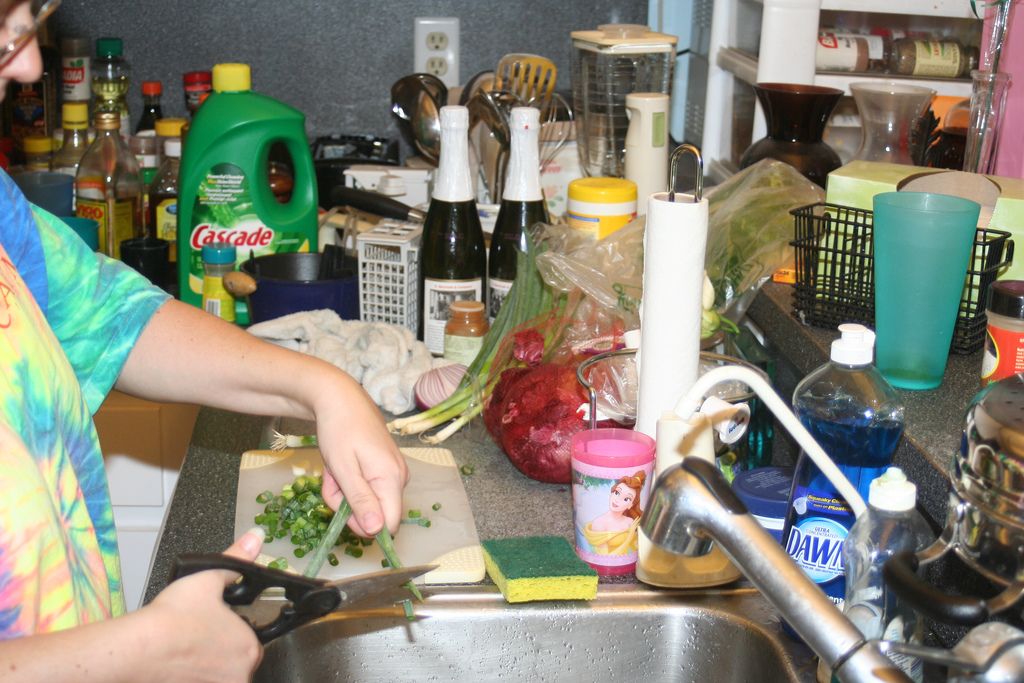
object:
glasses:
[0, 1, 59, 68]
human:
[0, 1, 407, 682]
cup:
[570, 428, 657, 576]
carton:
[571, 470, 651, 556]